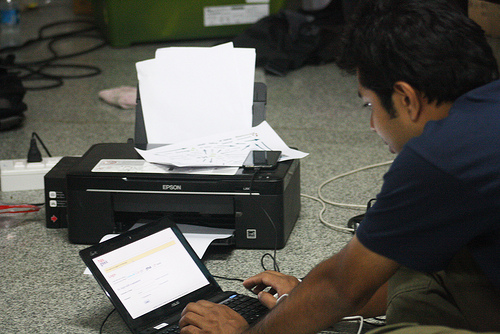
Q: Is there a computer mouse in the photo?
A: Yes, there is a computer mouse.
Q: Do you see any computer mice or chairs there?
A: Yes, there is a computer mouse.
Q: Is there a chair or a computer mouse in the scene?
A: Yes, there is a computer mouse.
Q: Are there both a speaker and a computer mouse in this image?
A: No, there is a computer mouse but no speakers.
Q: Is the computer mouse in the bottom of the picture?
A: Yes, the computer mouse is in the bottom of the image.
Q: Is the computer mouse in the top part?
A: No, the computer mouse is in the bottom of the image.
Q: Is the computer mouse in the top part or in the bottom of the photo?
A: The computer mouse is in the bottom of the image.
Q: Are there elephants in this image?
A: No, there are no elephants.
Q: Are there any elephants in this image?
A: No, there are no elephants.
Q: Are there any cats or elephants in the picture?
A: No, there are no elephants or cats.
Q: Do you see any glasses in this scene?
A: No, there are no glasses.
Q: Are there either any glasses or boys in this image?
A: No, there are no glasses or boys.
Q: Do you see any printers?
A: Yes, there is a printer.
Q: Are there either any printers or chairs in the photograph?
A: Yes, there is a printer.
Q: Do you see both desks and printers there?
A: No, there is a printer but no desks.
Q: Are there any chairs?
A: No, there are no chairs.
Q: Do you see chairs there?
A: No, there are no chairs.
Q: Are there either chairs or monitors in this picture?
A: No, there are no chairs or monitors.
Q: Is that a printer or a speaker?
A: That is a printer.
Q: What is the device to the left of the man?
A: The device is a printer.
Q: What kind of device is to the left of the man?
A: The device is a printer.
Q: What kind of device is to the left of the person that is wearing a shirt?
A: The device is a printer.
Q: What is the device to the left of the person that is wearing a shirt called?
A: The device is a printer.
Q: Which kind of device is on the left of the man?
A: The device is a printer.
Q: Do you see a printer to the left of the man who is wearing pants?
A: Yes, there is a printer to the left of the man.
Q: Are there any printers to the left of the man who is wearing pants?
A: Yes, there is a printer to the left of the man.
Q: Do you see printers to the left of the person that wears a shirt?
A: Yes, there is a printer to the left of the man.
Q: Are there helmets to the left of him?
A: No, there is a printer to the left of the man.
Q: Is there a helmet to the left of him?
A: No, there is a printer to the left of the man.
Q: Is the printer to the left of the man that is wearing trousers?
A: Yes, the printer is to the left of the man.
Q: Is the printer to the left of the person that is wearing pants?
A: Yes, the printer is to the left of the man.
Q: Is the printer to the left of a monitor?
A: No, the printer is to the left of the man.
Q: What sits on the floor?
A: The printer sits on the floor.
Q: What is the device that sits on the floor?
A: The device is a printer.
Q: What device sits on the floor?
A: The device is a printer.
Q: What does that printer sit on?
A: The printer sits on the floor.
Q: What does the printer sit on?
A: The printer sits on the floor.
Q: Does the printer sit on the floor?
A: Yes, the printer sits on the floor.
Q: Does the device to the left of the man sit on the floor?
A: Yes, the printer sits on the floor.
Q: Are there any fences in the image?
A: No, there are no fences.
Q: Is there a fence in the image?
A: No, there are no fences.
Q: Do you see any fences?
A: No, there are no fences.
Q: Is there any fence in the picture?
A: No, there are no fences.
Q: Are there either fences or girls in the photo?
A: No, there are no fences or girls.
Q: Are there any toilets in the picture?
A: No, there are no toilets.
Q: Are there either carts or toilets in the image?
A: No, there are no toilets or carts.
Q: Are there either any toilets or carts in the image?
A: No, there are no toilets or carts.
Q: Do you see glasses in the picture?
A: No, there are no glasses.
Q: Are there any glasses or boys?
A: No, there are no glasses or boys.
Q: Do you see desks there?
A: No, there are no desks.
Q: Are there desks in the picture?
A: No, there are no desks.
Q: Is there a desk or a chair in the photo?
A: No, there are no desks or chairs.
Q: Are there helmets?
A: No, there are no helmets.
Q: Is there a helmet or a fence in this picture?
A: No, there are no helmets or fences.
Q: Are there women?
A: No, there are no women.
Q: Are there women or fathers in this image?
A: No, there are no women or fathers.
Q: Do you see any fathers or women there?
A: No, there are no women or fathers.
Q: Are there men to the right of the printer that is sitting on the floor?
A: Yes, there is a man to the right of the printer.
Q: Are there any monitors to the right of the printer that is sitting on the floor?
A: No, there is a man to the right of the printer.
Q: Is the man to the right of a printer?
A: Yes, the man is to the right of a printer.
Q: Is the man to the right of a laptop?
A: No, the man is to the right of a printer.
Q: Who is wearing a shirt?
A: The man is wearing a shirt.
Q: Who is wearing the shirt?
A: The man is wearing a shirt.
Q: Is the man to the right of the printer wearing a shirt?
A: Yes, the man is wearing a shirt.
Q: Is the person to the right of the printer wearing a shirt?
A: Yes, the man is wearing a shirt.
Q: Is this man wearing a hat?
A: No, the man is wearing a shirt.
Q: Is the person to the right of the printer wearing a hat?
A: No, the man is wearing a shirt.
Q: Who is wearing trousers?
A: The man is wearing trousers.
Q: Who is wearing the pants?
A: The man is wearing trousers.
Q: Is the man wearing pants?
A: Yes, the man is wearing pants.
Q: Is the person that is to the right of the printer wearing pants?
A: Yes, the man is wearing pants.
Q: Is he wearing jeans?
A: No, the man is wearing pants.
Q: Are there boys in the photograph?
A: No, there are no boys.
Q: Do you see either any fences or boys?
A: No, there are no boys or fences.